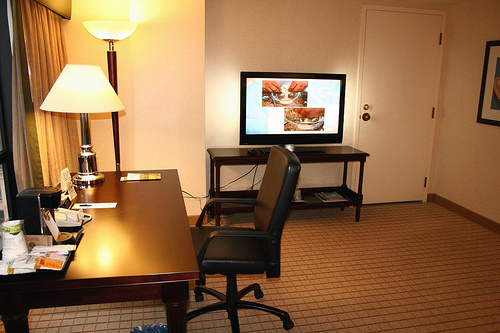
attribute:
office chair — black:
[190, 136, 298, 330]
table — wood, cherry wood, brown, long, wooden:
[1, 169, 206, 333]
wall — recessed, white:
[68, 0, 445, 210]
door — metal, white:
[355, 2, 439, 208]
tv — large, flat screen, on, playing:
[236, 67, 347, 141]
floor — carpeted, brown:
[14, 192, 500, 332]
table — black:
[206, 145, 370, 227]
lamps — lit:
[40, 9, 152, 187]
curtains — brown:
[1, 1, 91, 199]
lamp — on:
[42, 60, 124, 187]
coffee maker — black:
[17, 178, 82, 250]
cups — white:
[1, 222, 28, 270]